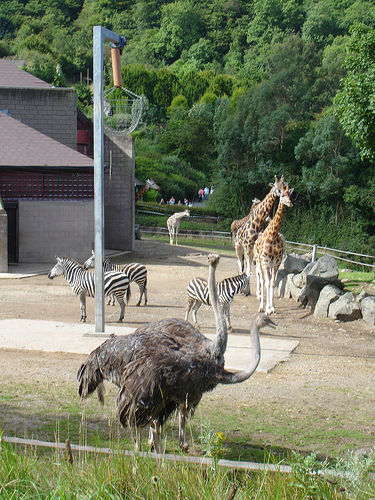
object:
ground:
[1, 240, 374, 495]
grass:
[0, 376, 375, 496]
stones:
[327, 291, 363, 325]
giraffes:
[233, 173, 288, 302]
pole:
[93, 23, 106, 335]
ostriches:
[95, 248, 230, 450]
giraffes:
[253, 181, 294, 316]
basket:
[103, 86, 144, 138]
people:
[203, 185, 209, 200]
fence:
[135, 224, 375, 276]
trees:
[215, 61, 314, 232]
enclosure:
[0, 224, 375, 500]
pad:
[0, 316, 302, 376]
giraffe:
[166, 209, 190, 246]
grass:
[141, 232, 375, 302]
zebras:
[47, 254, 132, 324]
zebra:
[184, 273, 252, 335]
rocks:
[360, 295, 375, 327]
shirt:
[204, 188, 209, 195]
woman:
[198, 188, 205, 203]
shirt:
[199, 189, 204, 195]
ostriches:
[76, 311, 279, 455]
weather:
[0, 0, 375, 499]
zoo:
[0, 0, 375, 493]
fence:
[0, 432, 372, 498]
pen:
[0, 222, 374, 498]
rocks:
[283, 251, 310, 274]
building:
[0, 57, 138, 274]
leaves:
[250, 64, 254, 76]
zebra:
[82, 248, 148, 307]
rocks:
[313, 283, 346, 318]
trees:
[292, 116, 363, 228]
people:
[209, 186, 214, 195]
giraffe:
[135, 177, 160, 203]